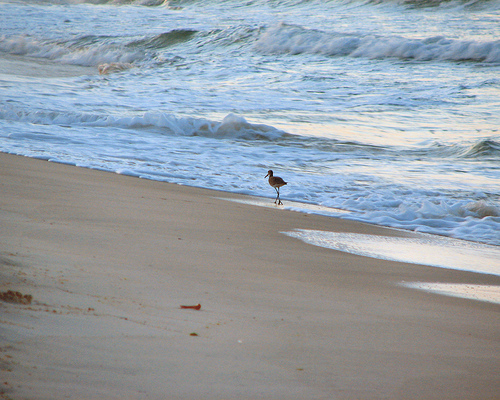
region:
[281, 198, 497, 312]
wet sand from receding wave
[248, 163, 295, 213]
lone bird on the shore line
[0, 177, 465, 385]
flat tan sand at the shore line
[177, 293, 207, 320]
red debris on flat tan sand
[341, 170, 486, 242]
foamy save at the shore line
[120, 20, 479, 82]
crashing wave in the ocean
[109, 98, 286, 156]
gentle wave in the ocean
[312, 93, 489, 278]
sunlight reflected off the water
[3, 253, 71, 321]
loose sand on flat tan sand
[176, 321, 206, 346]
small pebble on flat tan sand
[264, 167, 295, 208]
A small bird walking on the beach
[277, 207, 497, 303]
Water washing up onto the sand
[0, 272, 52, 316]
Clumps of sand forming a pile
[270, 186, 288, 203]
The tall thin legs of a bird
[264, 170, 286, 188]
A bird's brown body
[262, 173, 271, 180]
A bird's tiny beak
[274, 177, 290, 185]
The tail feathers of a bird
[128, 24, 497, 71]
A tall wave rising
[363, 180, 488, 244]
The white foam of a wave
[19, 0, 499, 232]
The wavy water of the sea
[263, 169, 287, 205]
Bird walking along shoreline at ocean.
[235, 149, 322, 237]
Bird on the beach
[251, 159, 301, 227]
Bird on the beach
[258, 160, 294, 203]
Bird on the beach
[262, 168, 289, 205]
lone bird on beach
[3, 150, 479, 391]
grey flat sandy beach front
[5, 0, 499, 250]
blue and white rushing ocean water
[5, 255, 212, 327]
various orange sticks and stones on beach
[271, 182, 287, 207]
long bird legs on sea bird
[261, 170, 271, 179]
long pointy beak on walking sea bird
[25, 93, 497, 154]
white rippled wave in water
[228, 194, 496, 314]
wet patches on beach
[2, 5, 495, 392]
sunny daytime beach scene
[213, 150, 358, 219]
sea bird standing in wet patch on beach